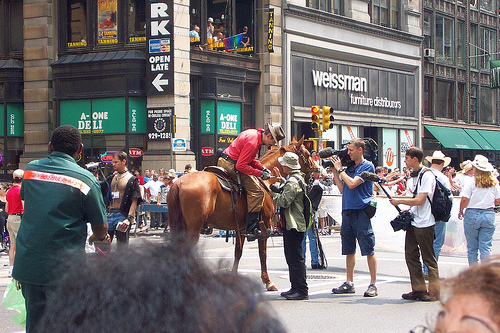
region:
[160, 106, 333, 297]
Man riding a horse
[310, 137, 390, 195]
Person hlding a camera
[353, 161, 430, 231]
Person holding a boom microphone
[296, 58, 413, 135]
Sign on a building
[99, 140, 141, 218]
Man with shirt opened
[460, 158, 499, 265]
Woman wearing blue jeans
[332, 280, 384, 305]
Tennis shoes on a man's feet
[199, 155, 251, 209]
Saddle on a horse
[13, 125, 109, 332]
a man in a green shirt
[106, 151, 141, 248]
a man in a black jacket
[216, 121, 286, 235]
a man in a red shirt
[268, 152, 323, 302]
a man in a beige jacket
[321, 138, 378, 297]
a man in a blue shirt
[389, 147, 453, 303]
a man in a white shirt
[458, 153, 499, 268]
a woman in a white shirt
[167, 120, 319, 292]
a cowboy riding a brown horse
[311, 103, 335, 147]
a traffic signal on a pole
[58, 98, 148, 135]
a green A-1 deli sign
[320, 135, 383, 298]
man with large video camera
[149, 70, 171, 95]
arrow pointing left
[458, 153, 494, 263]
woman wearing a hat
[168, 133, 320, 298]
brown colored horse with rider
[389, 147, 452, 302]
man with black backpack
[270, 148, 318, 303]
man with a tan hat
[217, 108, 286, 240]
man riding brown horse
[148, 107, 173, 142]
black sign with white writing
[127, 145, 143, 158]
red and white atm sign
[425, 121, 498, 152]
green canopy in front of building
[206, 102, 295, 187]
a guy riding a horse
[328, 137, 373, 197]
a guy holding a video camera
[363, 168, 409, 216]
a guy holding a large mic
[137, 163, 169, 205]
people standing behind a baracaid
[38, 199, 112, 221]
a guy wearing a green shirt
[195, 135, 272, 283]
a horse walking on the street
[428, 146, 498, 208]
people walking in the street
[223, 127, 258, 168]
a guy wearing a red shirt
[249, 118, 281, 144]
a guy wearing a tan hat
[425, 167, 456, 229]
a guy carrying a backpack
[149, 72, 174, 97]
Arrow on a sign pointing left.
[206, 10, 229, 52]
People looking out an upper story window.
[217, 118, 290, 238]
Man riding a horse.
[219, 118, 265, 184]
Man's red collard shirt.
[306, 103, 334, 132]
Stoplight on the corner.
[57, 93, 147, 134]
Green deli sign on a building.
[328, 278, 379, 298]
Man's grey tennis shoes.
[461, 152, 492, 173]
Woman's white cowboy hat.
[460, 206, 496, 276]
Woman's blue denim jeans.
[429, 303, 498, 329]
Woman's eyebrows near corner.